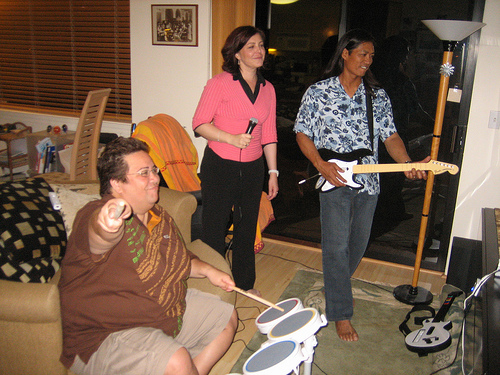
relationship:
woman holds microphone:
[190, 22, 279, 290] [245, 115, 257, 140]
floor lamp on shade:
[394, 17, 484, 307] [420, 18, 484, 43]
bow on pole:
[434, 56, 458, 79] [391, 49, 456, 304]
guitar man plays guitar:
[292, 27, 432, 341] [294, 141, 461, 191]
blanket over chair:
[128, 110, 295, 195] [66, 108, 198, 259]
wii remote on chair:
[48, 188, 63, 213] [3, 171, 242, 372]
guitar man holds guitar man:
[292, 27, 432, 341] [290, 27, 458, 339]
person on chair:
[38, 157, 245, 373] [3, 171, 242, 372]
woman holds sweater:
[190, 22, 279, 290] [187, 70, 277, 163]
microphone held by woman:
[228, 101, 280, 160] [192, 23, 284, 283]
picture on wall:
[146, 3, 201, 48] [138, 8, 202, 128]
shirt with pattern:
[296, 71, 395, 192] [315, 107, 369, 157]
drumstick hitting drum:
[218, 281, 283, 315] [251, 291, 304, 336]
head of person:
[95, 136, 160, 206] [55, 137, 239, 375]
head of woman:
[222, 26, 266, 66] [190, 22, 279, 290]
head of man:
[321, 21, 388, 99] [313, 33, 390, 107]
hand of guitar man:
[314, 159, 349, 189] [292, 27, 432, 341]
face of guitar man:
[343, 43, 372, 76] [292, 27, 432, 341]